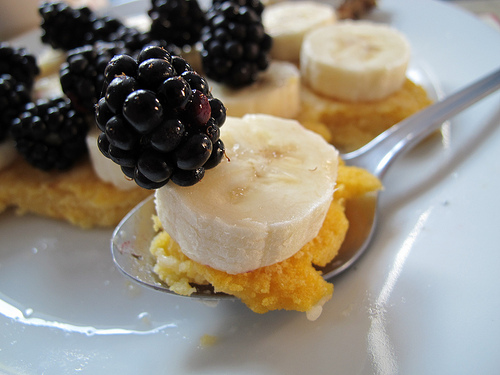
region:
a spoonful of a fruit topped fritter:
[90, 45, 495, 326]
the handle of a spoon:
[405, 75, 495, 125]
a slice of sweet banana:
[170, 110, 325, 270]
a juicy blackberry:
[90, 45, 225, 190]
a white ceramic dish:
[7, 245, 97, 350]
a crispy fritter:
[15, 175, 117, 220]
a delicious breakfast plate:
[0, 0, 495, 370]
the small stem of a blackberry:
[221, 147, 227, 162]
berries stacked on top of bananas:
[13, 3, 293, 194]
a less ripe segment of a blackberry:
[186, 89, 211, 124]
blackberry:
[105, 57, 243, 204]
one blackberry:
[86, 41, 281, 198]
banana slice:
[159, 178, 362, 282]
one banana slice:
[157, 173, 383, 258]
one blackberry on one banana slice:
[81, 66, 329, 258]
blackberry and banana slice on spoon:
[109, 34, 334, 277]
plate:
[22, 237, 136, 369]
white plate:
[22, 241, 132, 372]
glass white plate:
[34, 248, 137, 367]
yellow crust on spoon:
[174, 247, 364, 334]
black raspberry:
[99, 47, 228, 189]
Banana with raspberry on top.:
[96, 47, 339, 268]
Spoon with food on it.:
[99, 135, 406, 302]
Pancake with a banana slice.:
[304, 23, 422, 128]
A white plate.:
[369, 230, 498, 360]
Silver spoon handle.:
[359, 78, 496, 168]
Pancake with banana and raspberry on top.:
[102, 83, 379, 302]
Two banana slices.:
[269, 5, 410, 97]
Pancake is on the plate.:
[6, 173, 117, 227]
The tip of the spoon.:
[111, 195, 156, 306]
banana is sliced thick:
[150, 104, 385, 336]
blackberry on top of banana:
[96, 62, 241, 197]